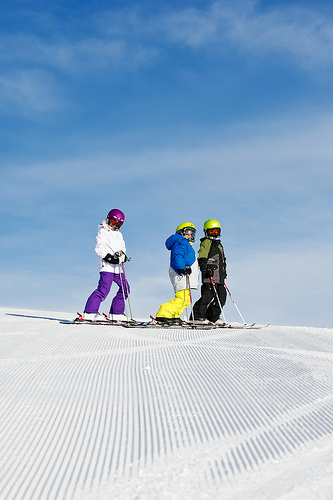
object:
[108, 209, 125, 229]
helmet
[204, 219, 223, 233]
helmet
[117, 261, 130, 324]
rod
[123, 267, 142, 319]
rod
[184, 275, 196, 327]
rod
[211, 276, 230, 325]
rod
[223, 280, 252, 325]
rod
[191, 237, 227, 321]
suit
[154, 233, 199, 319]
suit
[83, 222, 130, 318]
suit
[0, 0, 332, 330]
sky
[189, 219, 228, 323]
man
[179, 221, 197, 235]
helmet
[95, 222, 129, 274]
jacket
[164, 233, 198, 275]
jacket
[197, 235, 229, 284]
jacket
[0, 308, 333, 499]
snow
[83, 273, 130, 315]
pants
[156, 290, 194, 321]
pants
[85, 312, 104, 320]
boot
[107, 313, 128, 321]
boot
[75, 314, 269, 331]
skis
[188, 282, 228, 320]
pants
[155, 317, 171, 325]
boot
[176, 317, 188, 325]
boot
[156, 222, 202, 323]
woman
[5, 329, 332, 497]
pattern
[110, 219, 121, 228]
eye wear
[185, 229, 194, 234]
eye wear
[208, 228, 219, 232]
eye wear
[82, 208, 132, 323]
girl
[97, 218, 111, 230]
hood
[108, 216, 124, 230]
visor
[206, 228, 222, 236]
visor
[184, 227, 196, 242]
visor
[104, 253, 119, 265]
hand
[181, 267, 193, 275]
hand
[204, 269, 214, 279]
hand